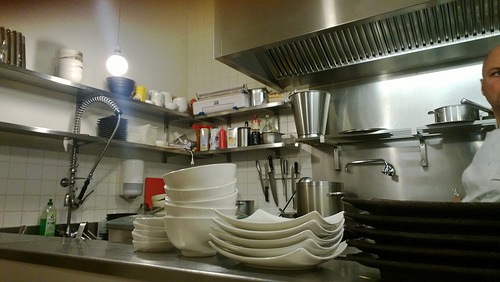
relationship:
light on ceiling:
[97, 45, 148, 88] [125, 0, 192, 30]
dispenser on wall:
[118, 147, 162, 224] [28, 142, 119, 214]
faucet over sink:
[57, 160, 101, 220] [28, 199, 134, 274]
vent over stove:
[248, 10, 454, 74] [317, 197, 396, 230]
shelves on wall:
[31, 66, 130, 116] [28, 142, 119, 214]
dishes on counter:
[97, 161, 344, 270] [13, 220, 88, 275]